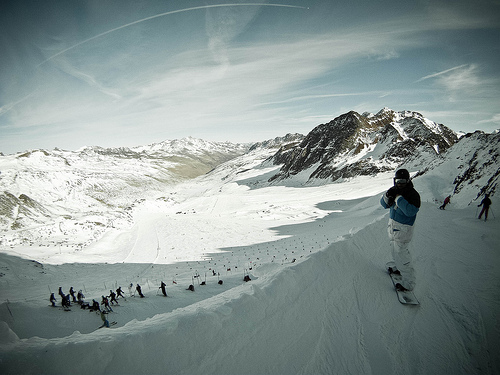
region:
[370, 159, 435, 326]
Man on snow board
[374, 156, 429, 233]
Blue winter ski jacket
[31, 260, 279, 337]
Group of skiiers and snowboarders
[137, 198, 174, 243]
Bright white snow on a sunny day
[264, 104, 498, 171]
Mountain on ski slope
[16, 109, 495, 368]
Ski slope ready for action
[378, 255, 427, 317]
snow board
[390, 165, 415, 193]
safety helmet and goggles for skiing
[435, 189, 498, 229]
Skiiers using ski poles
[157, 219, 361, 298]
Slolom flags on ski slope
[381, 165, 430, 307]
Snowboarder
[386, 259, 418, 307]
Snowboard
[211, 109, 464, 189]
Mountain top that's distant from the snowboarder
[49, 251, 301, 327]
Several snowboarders on ground level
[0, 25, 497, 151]
Clear sky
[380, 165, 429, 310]
Snowboarder standing on top of a hill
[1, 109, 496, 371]
Land consisting of snowy mountains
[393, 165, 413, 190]
Mask worn by the snowboarder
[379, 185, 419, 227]
Jacket worn by the snowboarder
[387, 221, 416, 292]
White pants worn by the snowboarder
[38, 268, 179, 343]
several skiers on a hillside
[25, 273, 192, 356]
several skiers on a snowy hillside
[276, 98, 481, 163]
a snowy peak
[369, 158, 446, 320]
a man on a snowboard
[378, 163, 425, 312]
a man riding a snowboard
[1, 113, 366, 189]
a snowy mountain range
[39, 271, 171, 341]
several people on skis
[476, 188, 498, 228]
a man on skis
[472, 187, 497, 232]
a man skiing down a hill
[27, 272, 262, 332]
People are walking around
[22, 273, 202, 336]
Everyone is wearing black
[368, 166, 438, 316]
This person is alone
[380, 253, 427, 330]
A white board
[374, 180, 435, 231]
This coat is white, light blue, and dark blue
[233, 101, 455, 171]
This mountain has less snow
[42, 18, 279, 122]
Sky has some clouds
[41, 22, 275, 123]
Clouds are white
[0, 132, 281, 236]
Mountains in the distance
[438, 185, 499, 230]
Two people here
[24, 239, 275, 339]
several people skiing in the snow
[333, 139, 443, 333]
a man on a snow board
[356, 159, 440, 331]
a man standing on a snow board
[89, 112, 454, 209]
mountains covered with snow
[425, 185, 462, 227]
a person skiing down a hill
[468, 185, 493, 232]
a person holding ski poles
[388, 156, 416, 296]
a person wearing white pants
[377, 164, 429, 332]
a person standing on a mound of snow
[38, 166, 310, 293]
a valley between tall mountains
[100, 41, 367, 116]
white clouds in a blue sky